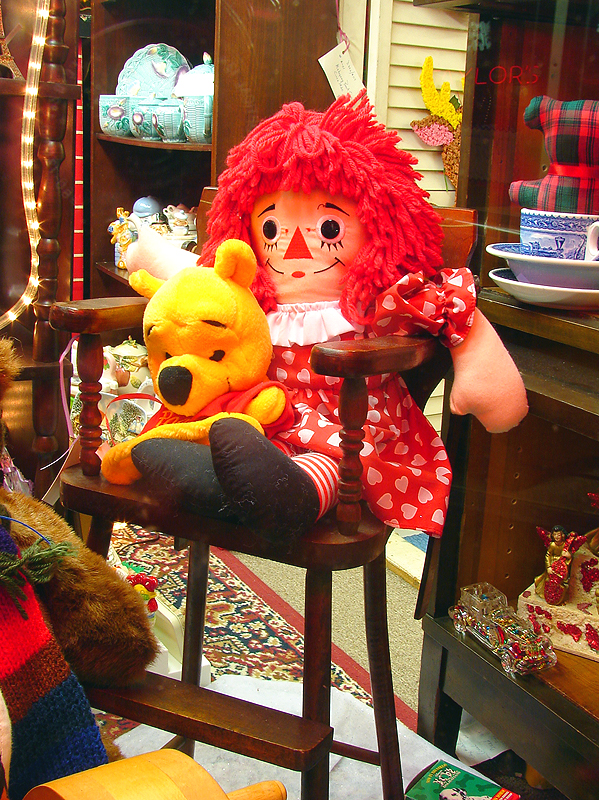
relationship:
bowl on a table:
[484, 242, 597, 289] [436, 276, 596, 609]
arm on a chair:
[305, 333, 442, 368] [29, 200, 475, 798]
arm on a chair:
[49, 296, 149, 331] [29, 200, 475, 798]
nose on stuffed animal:
[157, 366, 192, 403] [100, 238, 294, 485]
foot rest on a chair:
[77, 661, 332, 773] [40, 281, 400, 794]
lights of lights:
[0, 0, 50, 331] [0, 3, 51, 331]